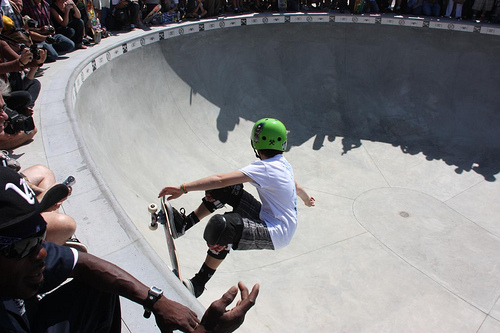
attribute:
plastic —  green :
[249, 117, 286, 152]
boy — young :
[158, 116, 316, 300]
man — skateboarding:
[156, 117, 315, 299]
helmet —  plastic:
[241, 113, 315, 155]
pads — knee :
[192, 214, 234, 247]